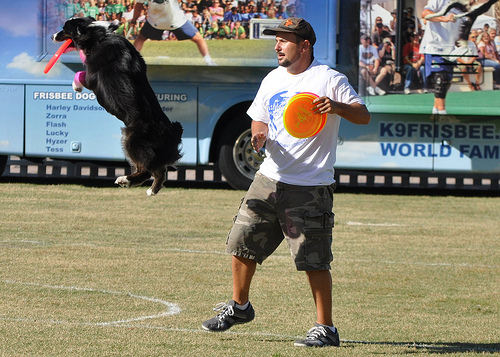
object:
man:
[200, 17, 370, 347]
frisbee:
[283, 92, 327, 140]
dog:
[49, 17, 182, 196]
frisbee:
[42, 39, 71, 74]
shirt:
[246, 58, 363, 186]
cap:
[261, 18, 317, 46]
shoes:
[201, 300, 340, 347]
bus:
[1, 0, 499, 191]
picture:
[357, 0, 500, 116]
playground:
[0, 177, 500, 357]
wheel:
[218, 112, 266, 191]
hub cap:
[233, 129, 267, 181]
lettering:
[268, 91, 289, 132]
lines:
[0, 280, 181, 327]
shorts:
[226, 170, 334, 272]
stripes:
[222, 314, 246, 324]